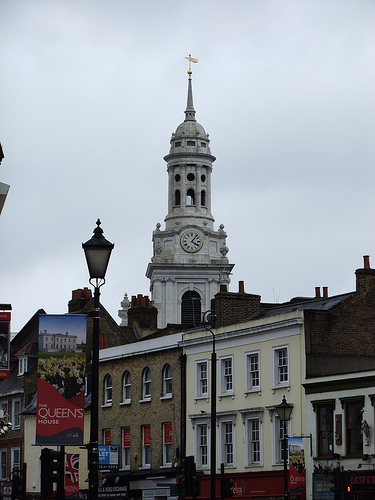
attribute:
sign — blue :
[32, 312, 93, 447]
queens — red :
[31, 310, 87, 452]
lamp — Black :
[269, 391, 295, 423]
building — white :
[98, 333, 374, 452]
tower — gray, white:
[115, 35, 238, 231]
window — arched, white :
[179, 181, 199, 212]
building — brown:
[107, 357, 171, 455]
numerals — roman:
[182, 237, 195, 250]